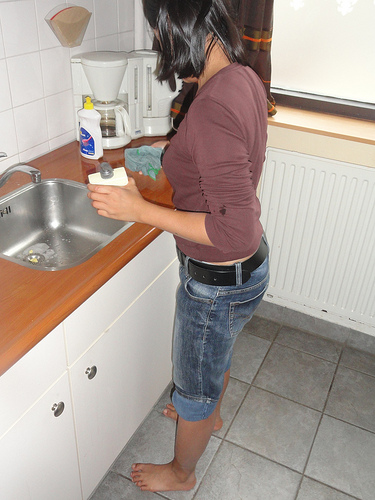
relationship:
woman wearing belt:
[87, 0, 272, 492] [173, 231, 269, 286]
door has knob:
[68, 256, 181, 500] [85, 364, 99, 382]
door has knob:
[2, 369, 84, 500] [50, 400, 66, 418]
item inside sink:
[25, 248, 39, 264] [0, 174, 135, 274]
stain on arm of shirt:
[218, 203, 230, 218] [159, 64, 269, 262]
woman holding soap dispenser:
[87, 0, 272, 492] [86, 160, 129, 189]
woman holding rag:
[87, 0, 272, 492] [124, 144, 164, 182]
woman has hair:
[87, 0, 272, 492] [141, 1, 250, 82]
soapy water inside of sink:
[14, 235, 71, 266] [0, 174, 135, 274]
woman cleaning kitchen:
[87, 0, 272, 492] [1, 0, 374, 499]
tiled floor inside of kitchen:
[85, 315, 374, 498] [1, 0, 374, 499]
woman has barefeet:
[87, 0, 272, 492] [129, 461, 197, 491]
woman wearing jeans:
[87, 0, 272, 492] [169, 242, 270, 421]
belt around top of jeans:
[173, 231, 269, 286] [169, 242, 270, 421]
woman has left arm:
[87, 0, 272, 492] [135, 97, 257, 254]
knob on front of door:
[85, 364, 99, 382] [68, 256, 181, 500]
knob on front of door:
[50, 400, 66, 418] [2, 369, 84, 500]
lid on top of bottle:
[81, 94, 96, 112] [75, 95, 104, 160]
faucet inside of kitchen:
[1, 147, 43, 190] [1, 0, 374, 499]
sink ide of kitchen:
[0, 174, 135, 274] [1, 0, 374, 499]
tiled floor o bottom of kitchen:
[85, 315, 374, 498] [1, 0, 374, 499]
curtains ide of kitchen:
[219, 0, 279, 120] [1, 0, 374, 499]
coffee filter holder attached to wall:
[44, 1, 94, 49] [0, 1, 134, 179]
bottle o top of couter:
[75, 95, 104, 160] [1, 133, 176, 382]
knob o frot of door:
[85, 364, 99, 382] [68, 256, 181, 500]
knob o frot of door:
[50, 400, 66, 418] [2, 369, 84, 500]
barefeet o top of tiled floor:
[131, 402, 224, 492] [85, 315, 374, 498]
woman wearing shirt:
[87, 0, 272, 492] [159, 64, 269, 262]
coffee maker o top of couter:
[69, 49, 131, 150] [1, 133, 176, 382]